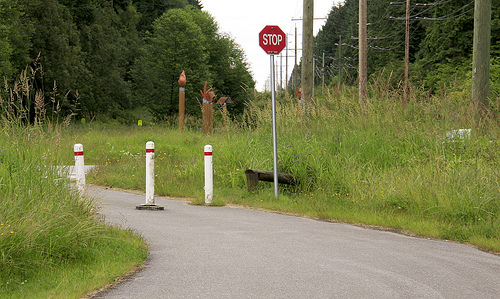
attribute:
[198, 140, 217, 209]
pole — white, metal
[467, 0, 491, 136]
pole — long, wooden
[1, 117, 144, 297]
grass — green, tall, brown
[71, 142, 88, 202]
white metalpole — metal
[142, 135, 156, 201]
white metalpole — metal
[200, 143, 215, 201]
white metalpole — metal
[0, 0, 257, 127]
trees — green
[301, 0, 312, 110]
pole — three, utility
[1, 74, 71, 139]
grass — tall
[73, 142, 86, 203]
pole — white, red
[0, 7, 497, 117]
trees — growing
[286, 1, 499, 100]
trees — green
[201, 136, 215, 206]
pole — wooden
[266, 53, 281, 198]
pole — long, sliver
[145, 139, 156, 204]
pole — red, white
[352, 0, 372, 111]
telephone pole — long, wooden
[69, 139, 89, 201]
pole — white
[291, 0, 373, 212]
pole — wooden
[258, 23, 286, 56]
sign — red, white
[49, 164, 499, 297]
road — edge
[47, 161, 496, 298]
trail — asphalt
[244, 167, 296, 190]
broken post — wooden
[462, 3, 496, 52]
post — wooden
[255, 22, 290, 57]
sign — red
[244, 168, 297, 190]
tree trunk — black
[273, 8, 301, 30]
phone lines — wooden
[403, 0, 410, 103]
telephone pole — wooden, long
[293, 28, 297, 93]
pole — wooden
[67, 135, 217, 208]
blockades — white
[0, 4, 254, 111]
trees — green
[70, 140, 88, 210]
post — white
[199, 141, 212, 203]
pole — metal, white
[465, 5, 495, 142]
pole — wooden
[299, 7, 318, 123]
post — wooden